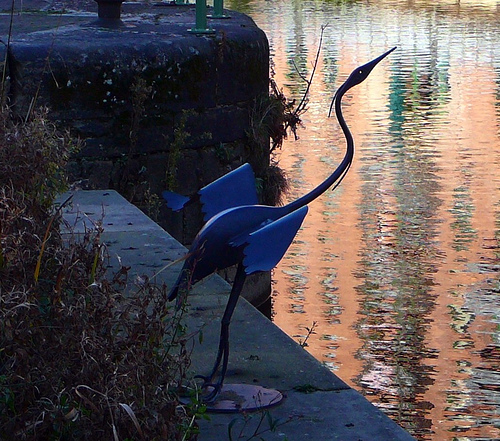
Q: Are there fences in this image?
A: No, there are no fences.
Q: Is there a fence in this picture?
A: No, there are no fences.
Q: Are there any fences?
A: No, there are no fences.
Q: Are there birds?
A: Yes, there is a bird.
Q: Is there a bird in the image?
A: Yes, there is a bird.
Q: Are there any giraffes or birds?
A: Yes, there is a bird.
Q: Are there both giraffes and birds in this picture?
A: No, there is a bird but no giraffes.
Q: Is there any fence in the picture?
A: No, there are no fences.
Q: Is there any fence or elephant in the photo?
A: No, there are no fences or elephants.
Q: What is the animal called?
A: The animal is a bird.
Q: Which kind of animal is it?
A: The animal is a bird.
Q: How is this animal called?
A: This is a bird.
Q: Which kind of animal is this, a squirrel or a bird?
A: This is a bird.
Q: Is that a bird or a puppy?
A: That is a bird.